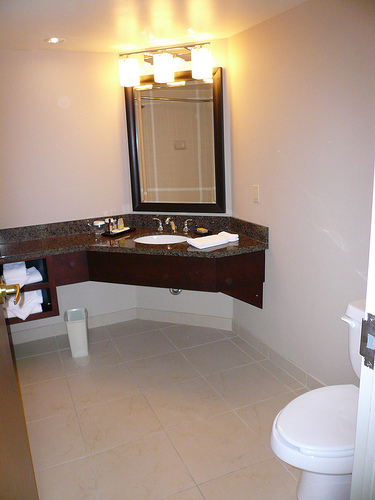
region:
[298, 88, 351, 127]
part of a wall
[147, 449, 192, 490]
part of a floor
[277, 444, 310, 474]
edge of a toilet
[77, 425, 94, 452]
part of a floor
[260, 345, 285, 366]
edge of a wall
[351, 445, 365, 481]
part of an edge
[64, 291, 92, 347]
part of a bin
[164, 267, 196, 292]
part of a board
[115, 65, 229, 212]
a mirror on the wall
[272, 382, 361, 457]
a white toilet lid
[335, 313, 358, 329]
a white plastic flushing handle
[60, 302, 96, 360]
a white trash can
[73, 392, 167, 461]
a white tile on the floor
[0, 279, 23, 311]
a gold door handle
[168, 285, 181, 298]
a metal pipe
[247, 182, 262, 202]
a white electrical socket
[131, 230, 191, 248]
a white sink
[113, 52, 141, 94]
a yellow light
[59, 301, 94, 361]
White wastebasket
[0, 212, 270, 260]
Granite counter top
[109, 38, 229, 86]
Three lamp light fixture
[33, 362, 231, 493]
Area of beige tile flooring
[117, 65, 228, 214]
Wall mirror with dark wood frame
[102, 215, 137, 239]
Tray of toiletries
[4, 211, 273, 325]
Bathroom sink and counter attached to wall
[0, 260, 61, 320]
Two shelves of white towels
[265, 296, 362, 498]
White toilet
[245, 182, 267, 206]
Electrical wall socket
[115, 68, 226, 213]
A large black-framed mirror above the sink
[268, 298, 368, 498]
A white ceramic toilet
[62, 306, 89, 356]
A white plastic trash bin with no bag beneath the counter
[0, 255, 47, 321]
White towels on shelves under the counter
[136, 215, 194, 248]
A white sink with silver faucets in a brown counter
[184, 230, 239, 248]
A white towel on the counter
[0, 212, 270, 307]
A brown marbled counter top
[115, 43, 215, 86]
A switched-on light with three lighting elements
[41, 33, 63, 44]
A round light in the white ceiling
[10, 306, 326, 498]
A beige floor with large tiles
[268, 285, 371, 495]
a white porcelain toilet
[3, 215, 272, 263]
a black granite countertop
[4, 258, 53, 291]
a stack of white towels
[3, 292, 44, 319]
a stack of white towels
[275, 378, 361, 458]
a white toilet seat lid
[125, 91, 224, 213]
a dark wood framed mirror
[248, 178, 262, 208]
a wall mounted electrical outlet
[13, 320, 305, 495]
a beige tiled floor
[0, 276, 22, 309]
a brass door handle